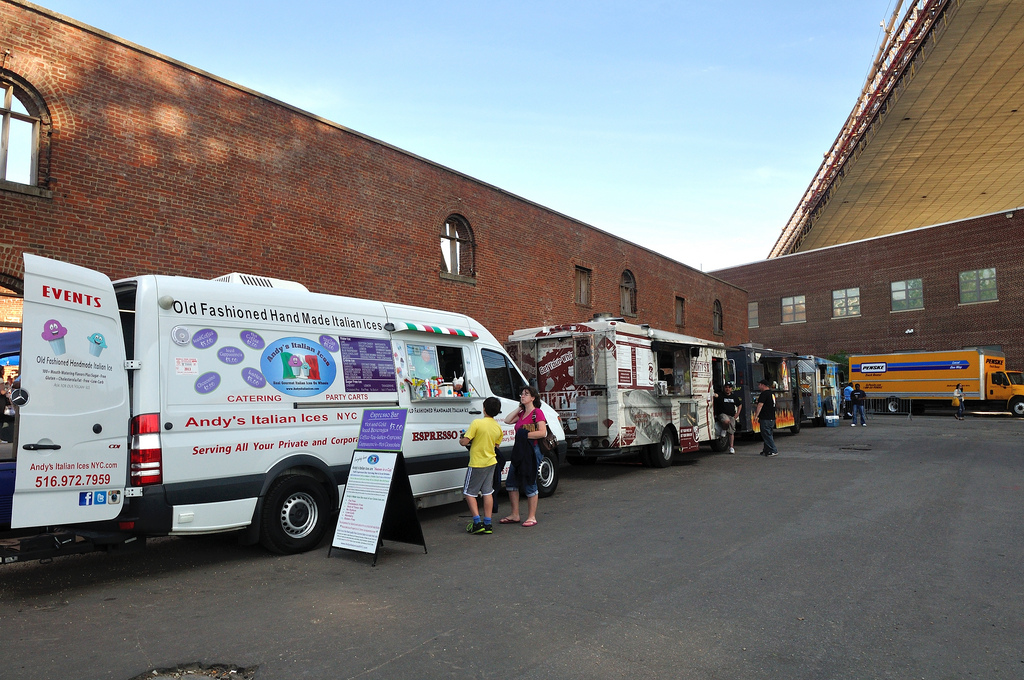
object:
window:
[438, 217, 476, 276]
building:
[11, 89, 1009, 353]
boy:
[755, 380, 778, 457]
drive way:
[455, 436, 1007, 675]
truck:
[24, 275, 559, 536]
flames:
[306, 355, 321, 379]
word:
[202, 304, 273, 321]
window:
[888, 277, 926, 310]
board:
[324, 405, 426, 566]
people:
[504, 386, 556, 523]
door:
[16, 283, 136, 537]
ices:
[262, 340, 334, 397]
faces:
[262, 334, 333, 397]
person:
[714, 380, 742, 453]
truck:
[537, 320, 732, 469]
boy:
[462, 396, 503, 535]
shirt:
[465, 420, 501, 466]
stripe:
[850, 360, 969, 373]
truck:
[848, 346, 1018, 415]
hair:
[517, 387, 542, 409]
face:
[518, 390, 533, 408]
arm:
[528, 415, 547, 439]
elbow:
[534, 429, 549, 441]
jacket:
[514, 428, 537, 483]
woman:
[503, 388, 560, 514]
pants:
[503, 435, 541, 501]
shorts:
[466, 460, 498, 496]